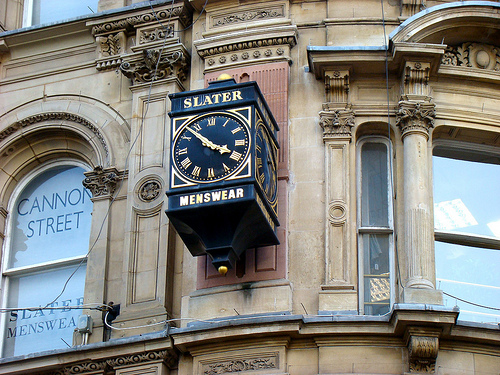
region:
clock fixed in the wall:
[166, 93, 257, 220]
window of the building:
[354, 130, 396, 327]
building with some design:
[319, 23, 434, 348]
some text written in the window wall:
[20, 145, 107, 354]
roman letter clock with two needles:
[168, 114, 261, 194]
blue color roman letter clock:
[161, 90, 261, 207]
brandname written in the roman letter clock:
[169, 68, 292, 258]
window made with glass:
[361, 131, 405, 326]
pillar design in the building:
[401, 56, 444, 363]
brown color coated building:
[283, 9, 347, 292]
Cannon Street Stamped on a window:
[7, 160, 103, 245]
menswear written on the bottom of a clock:
[172, 178, 247, 212]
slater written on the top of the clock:
[176, 87, 249, 114]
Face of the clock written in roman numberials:
[170, 107, 256, 186]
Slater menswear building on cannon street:
[0, 0, 499, 373]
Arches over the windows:
[1, 86, 133, 351]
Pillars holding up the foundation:
[379, 40, 464, 354]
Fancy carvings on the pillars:
[313, 95, 438, 149]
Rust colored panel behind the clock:
[181, 54, 300, 294]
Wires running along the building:
[0, 295, 497, 371]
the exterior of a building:
[0, 0, 499, 374]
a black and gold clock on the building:
[165, 72, 280, 274]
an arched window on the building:
[0, 156, 95, 358]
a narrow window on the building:
[355, 134, 395, 316]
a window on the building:
[431, 137, 498, 323]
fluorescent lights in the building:
[432, 197, 477, 230]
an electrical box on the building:
[76, 314, 92, 335]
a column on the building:
[395, 98, 445, 305]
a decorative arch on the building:
[386, 0, 498, 80]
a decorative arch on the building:
[0, 93, 127, 206]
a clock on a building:
[158, 69, 280, 281]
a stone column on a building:
[305, 55, 371, 335]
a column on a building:
[387, 40, 460, 365]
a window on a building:
[350, 123, 400, 333]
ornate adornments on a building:
[83, 13, 200, 83]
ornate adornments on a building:
[191, 11, 306, 71]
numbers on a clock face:
[167, 115, 252, 180]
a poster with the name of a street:
[10, 187, 101, 236]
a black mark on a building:
[235, 278, 262, 308]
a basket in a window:
[360, 266, 402, 313]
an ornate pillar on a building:
[315, 46, 362, 316]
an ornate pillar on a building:
[390, 40, 460, 355]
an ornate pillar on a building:
[80, 165, 120, 374]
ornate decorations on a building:
[83, 8, 197, 81]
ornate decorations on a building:
[200, 4, 298, 73]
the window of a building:
[352, 119, 389, 326]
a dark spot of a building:
[227, 282, 263, 307]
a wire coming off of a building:
[22, 40, 191, 326]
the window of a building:
[6, 163, 96, 356]